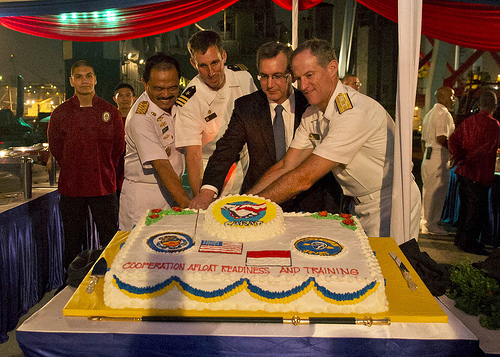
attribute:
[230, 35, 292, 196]
men — nine, four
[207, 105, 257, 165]
uniform — white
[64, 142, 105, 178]
jacket — red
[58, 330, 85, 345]
cloth — blue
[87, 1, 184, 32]
sash — red, hanging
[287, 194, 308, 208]
suit — brown, dark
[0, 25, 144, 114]
spectacle — evening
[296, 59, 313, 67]
skin — light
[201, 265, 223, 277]
writing — red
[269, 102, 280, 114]
neck tie — blue, black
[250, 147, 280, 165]
coat — black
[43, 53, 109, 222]
worker — service, standing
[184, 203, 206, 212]
knife — silver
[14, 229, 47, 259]
skirt — blue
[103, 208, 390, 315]
cake — iced, large, trimmed, rectangular, rectangle